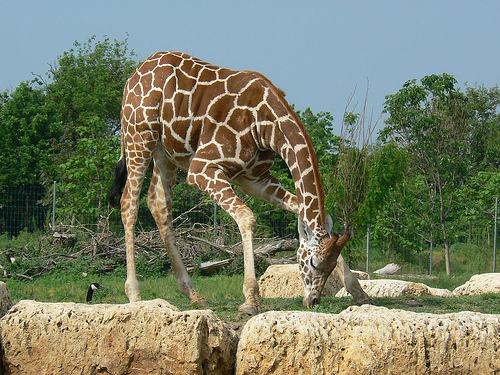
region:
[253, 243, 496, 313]
rock on the ground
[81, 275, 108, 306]
bird behind the giraffe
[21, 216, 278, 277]
branches on the ground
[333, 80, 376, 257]
branches on tree without leaves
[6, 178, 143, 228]
fence behind the giraffe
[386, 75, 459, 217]
thin tree behind the giraffe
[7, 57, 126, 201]
thick trees behind the giraffe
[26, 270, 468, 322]
green lawn giraffe stands on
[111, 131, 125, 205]
The tail fo the giraffe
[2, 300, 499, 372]
Large stones near the giraffe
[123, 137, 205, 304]
The rear legs of the giraffe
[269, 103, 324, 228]
The giraffe has a long neck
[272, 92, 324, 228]
The mane of the giraffe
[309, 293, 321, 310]
The nose of the giraffe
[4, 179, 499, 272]
A fence behidn the giraffe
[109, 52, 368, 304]
A giraffe eating the grass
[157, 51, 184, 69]
The spot is brown.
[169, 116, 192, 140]
The spot is brown.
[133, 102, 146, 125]
The spot is brown.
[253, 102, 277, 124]
The spot is brown.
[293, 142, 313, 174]
The spot is brown.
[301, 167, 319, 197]
The spot is brown.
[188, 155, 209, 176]
The spot is brown.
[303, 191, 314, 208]
The spot is brown.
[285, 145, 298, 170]
The spot is brown.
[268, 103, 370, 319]
The giraffe is grazing.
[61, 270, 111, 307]
The duck is behind the stone.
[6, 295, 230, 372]
The big rock is pitted.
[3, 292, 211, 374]
The big rock is brown.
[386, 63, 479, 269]
The trees are green and in leaf.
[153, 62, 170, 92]
The spot is brown.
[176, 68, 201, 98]
The spot is brown.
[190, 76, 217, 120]
The spot is brown.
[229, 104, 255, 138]
The spot is brown.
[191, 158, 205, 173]
The spot is brown.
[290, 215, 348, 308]
the giraffe grazing off the grass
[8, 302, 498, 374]
the rocks in front of the giraffe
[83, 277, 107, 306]
the head of the duck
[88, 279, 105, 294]
the white and black face of the duck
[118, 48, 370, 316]
the brown patches on the whtie lines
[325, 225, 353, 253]
the horns on the head of the giraffe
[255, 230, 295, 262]
the stump of the tree between the legs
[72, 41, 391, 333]
the giraffe has its head down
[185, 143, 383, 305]
the giraffe's knees are pent forward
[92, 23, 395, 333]
the giraffe has brown spots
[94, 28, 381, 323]
the giraffe has a long neck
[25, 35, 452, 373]
the giraffe is in a wildlife park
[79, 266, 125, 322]
the neck of a bird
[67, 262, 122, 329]
the bird has a black and white face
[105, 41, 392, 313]
tall giraffe is standing on the grass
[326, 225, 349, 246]
horns on the head of the giraffe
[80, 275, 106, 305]
black and white head of the bird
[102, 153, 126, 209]
black tail of the giraffe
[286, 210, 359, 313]
head of the giraffe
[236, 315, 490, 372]
large white and tan rock on the ground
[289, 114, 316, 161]
mane of the giraffe on the back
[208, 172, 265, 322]
leg on the giraffe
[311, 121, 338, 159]
tree with green leaves in the background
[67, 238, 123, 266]
sticks and brush behind the giraffe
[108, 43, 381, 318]
giraffe bending forward with head down